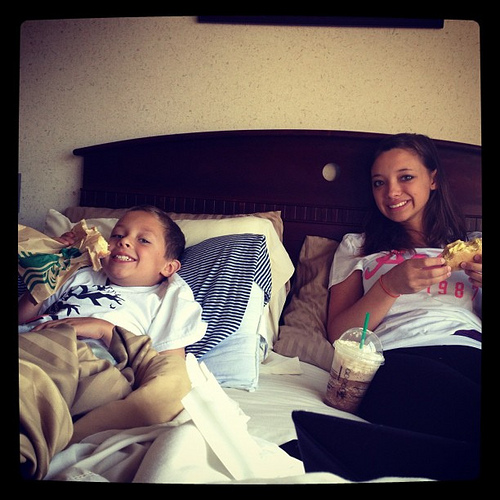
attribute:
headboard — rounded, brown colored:
[68, 120, 490, 242]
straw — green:
[356, 309, 371, 346]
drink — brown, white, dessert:
[321, 326, 383, 412]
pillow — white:
[168, 229, 278, 400]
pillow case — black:
[162, 227, 277, 359]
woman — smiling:
[328, 132, 485, 418]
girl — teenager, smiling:
[321, 128, 483, 450]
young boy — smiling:
[5, 206, 207, 483]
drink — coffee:
[321, 305, 387, 418]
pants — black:
[289, 330, 484, 481]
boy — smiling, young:
[20, 203, 210, 478]